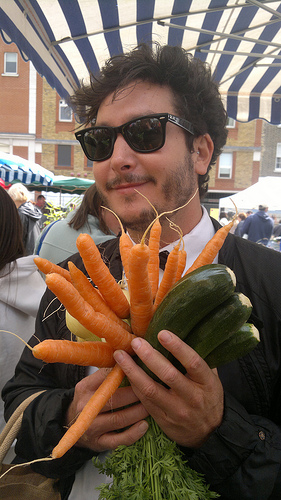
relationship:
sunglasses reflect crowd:
[73, 112, 204, 163] [125, 117, 163, 151]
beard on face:
[130, 148, 192, 232] [88, 73, 214, 226]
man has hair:
[1, 40, 280, 495] [71, 41, 230, 195]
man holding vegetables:
[1, 40, 280, 495] [33, 214, 258, 499]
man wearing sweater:
[232, 201, 275, 246] [234, 212, 277, 235]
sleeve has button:
[179, 391, 280, 497] [255, 427, 268, 443]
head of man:
[67, 42, 229, 225] [1, 40, 280, 495]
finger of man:
[153, 327, 211, 382] [1, 40, 280, 495]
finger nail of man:
[155, 327, 176, 346] [1, 40, 280, 495]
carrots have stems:
[28, 188, 235, 459] [128, 183, 166, 218]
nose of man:
[110, 134, 137, 175] [1, 40, 280, 495]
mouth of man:
[105, 180, 155, 192] [1, 40, 280, 495]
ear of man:
[190, 130, 215, 179] [1, 40, 280, 495]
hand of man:
[111, 328, 227, 452] [1, 40, 280, 495]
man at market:
[1, 40, 280, 495] [0, 150, 279, 250]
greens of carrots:
[95, 417, 224, 499] [28, 188, 235, 459]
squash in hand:
[145, 261, 263, 370] [111, 328, 227, 452]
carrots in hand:
[28, 188, 235, 459] [65, 362, 151, 456]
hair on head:
[71, 41, 230, 195] [67, 42, 229, 225]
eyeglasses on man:
[73, 112, 204, 163] [1, 40, 280, 495]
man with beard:
[1, 40, 280, 495] [130, 148, 192, 232]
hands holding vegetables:
[111, 328, 227, 452] [33, 214, 258, 499]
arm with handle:
[3, 275, 146, 475] [1, 390, 48, 469]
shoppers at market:
[0, 180, 53, 260] [0, 150, 279, 250]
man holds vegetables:
[1, 40, 280, 495] [33, 214, 258, 499]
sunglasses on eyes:
[73, 112, 204, 163] [87, 130, 161, 148]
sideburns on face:
[180, 131, 198, 181] [88, 73, 214, 226]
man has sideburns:
[1, 40, 280, 495] [180, 131, 198, 181]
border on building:
[25, 62, 38, 160] [1, 34, 263, 189]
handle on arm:
[1, 390, 48, 469] [3, 275, 146, 475]